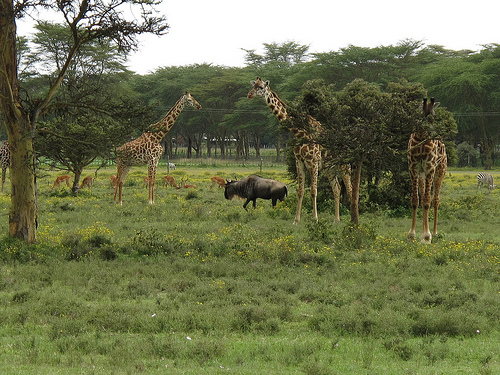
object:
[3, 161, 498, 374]
grass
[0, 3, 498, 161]
trees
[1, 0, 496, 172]
background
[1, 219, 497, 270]
flowers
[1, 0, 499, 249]
trees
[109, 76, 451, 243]
giraffes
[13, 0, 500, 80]
sky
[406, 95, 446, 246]
giraffe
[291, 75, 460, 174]
leaves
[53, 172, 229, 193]
gazelles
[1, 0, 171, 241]
tree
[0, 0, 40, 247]
trunk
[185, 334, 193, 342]
paper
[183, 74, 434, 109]
horns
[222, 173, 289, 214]
animal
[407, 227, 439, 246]
feet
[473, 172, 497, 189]
zebra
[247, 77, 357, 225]
giraffe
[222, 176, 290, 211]
wildebeest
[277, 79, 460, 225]
tree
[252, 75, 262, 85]
horns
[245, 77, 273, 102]
head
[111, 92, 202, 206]
giraffe